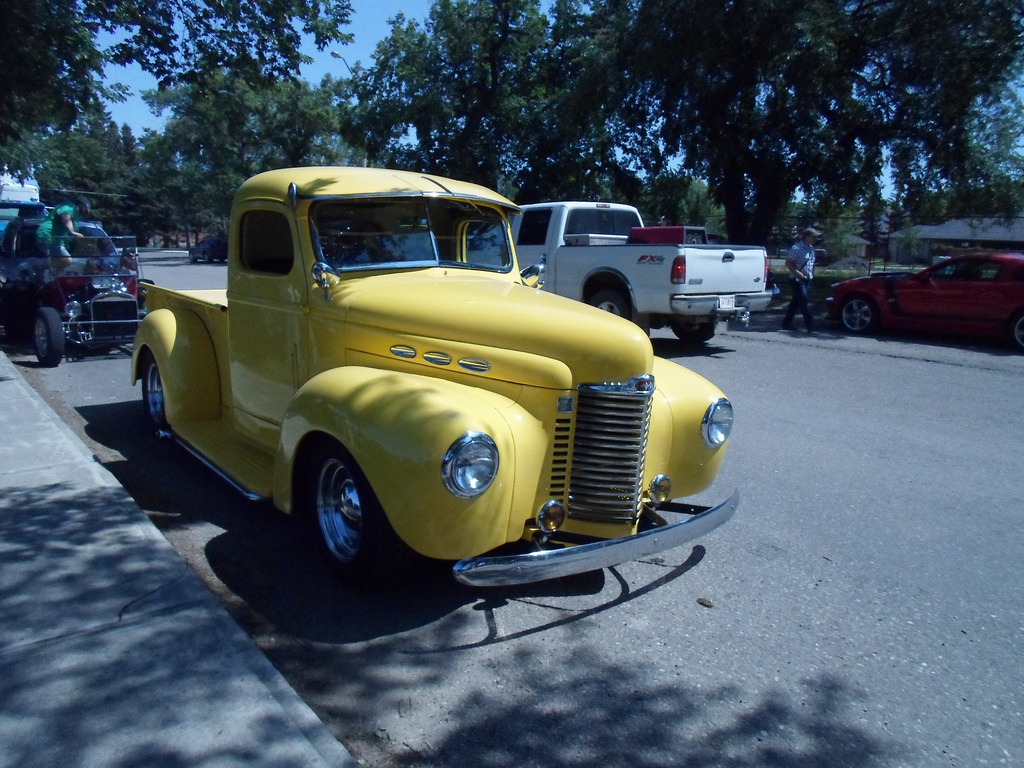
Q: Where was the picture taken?
A: It was taken at the pavement.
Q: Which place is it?
A: It is a pavement.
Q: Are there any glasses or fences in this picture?
A: No, there are no fences or glasses.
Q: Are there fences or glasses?
A: No, there are no fences or glasses.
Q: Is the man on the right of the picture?
A: Yes, the man is on the right of the image.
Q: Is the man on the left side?
A: No, the man is on the right of the image.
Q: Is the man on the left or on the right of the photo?
A: The man is on the right of the image.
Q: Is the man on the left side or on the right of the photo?
A: The man is on the right of the image.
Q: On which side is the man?
A: The man is on the right of the image.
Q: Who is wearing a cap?
A: The man is wearing a cap.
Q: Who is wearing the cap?
A: The man is wearing a cap.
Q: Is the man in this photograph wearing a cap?
A: Yes, the man is wearing a cap.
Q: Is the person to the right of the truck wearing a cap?
A: Yes, the man is wearing a cap.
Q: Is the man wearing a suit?
A: No, the man is wearing a cap.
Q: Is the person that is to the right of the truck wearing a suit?
A: No, the man is wearing a cap.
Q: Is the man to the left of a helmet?
A: No, the man is to the left of the car.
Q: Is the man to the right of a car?
A: No, the man is to the left of a car.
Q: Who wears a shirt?
A: The man wears a shirt.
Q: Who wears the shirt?
A: The man wears a shirt.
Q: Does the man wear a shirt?
A: Yes, the man wears a shirt.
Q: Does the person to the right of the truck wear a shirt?
A: Yes, the man wears a shirt.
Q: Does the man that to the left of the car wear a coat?
A: No, the man wears a shirt.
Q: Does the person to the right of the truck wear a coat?
A: No, the man wears a shirt.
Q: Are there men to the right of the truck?
A: Yes, there is a man to the right of the truck.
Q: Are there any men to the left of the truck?
A: No, the man is to the right of the truck.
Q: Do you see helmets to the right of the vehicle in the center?
A: No, there is a man to the right of the truck.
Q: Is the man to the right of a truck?
A: Yes, the man is to the right of a truck.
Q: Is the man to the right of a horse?
A: No, the man is to the right of a truck.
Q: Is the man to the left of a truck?
A: No, the man is to the right of a truck.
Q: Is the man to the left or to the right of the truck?
A: The man is to the right of the truck.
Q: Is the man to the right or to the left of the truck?
A: The man is to the right of the truck.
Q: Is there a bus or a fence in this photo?
A: No, there are no fences or buses.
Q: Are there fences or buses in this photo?
A: No, there are no fences or buses.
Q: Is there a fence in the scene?
A: No, there are no fences.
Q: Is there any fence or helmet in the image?
A: No, there are no fences or helmets.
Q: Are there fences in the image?
A: No, there are no fences.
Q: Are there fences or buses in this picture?
A: No, there are no fences or buses.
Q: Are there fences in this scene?
A: No, there are no fences.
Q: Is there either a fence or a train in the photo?
A: No, there are no fences or trains.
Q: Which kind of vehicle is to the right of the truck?
A: The vehicles are cars.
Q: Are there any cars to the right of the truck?
A: Yes, there are cars to the right of the truck.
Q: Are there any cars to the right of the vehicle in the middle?
A: Yes, there are cars to the right of the truck.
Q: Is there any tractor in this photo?
A: No, there are no tractors.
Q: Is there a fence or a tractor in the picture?
A: No, there are no tractors or fences.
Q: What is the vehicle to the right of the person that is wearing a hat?
A: The vehicle is a car.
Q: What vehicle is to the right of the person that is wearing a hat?
A: The vehicle is a car.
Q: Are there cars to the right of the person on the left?
A: Yes, there is a car to the right of the person.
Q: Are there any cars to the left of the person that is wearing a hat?
A: No, the car is to the right of the person.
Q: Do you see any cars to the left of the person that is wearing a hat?
A: No, the car is to the right of the person.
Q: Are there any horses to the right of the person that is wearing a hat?
A: No, there is a car to the right of the person.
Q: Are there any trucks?
A: Yes, there is a truck.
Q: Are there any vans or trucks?
A: Yes, there is a truck.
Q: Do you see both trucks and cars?
A: Yes, there are both a truck and cars.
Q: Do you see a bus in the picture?
A: No, there are no buses.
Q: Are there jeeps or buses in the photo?
A: No, there are no buses or jeeps.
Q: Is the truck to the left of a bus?
A: No, the truck is to the left of the car.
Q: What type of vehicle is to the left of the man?
A: The vehicle is a truck.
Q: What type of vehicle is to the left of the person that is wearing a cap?
A: The vehicle is a truck.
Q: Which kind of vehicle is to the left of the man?
A: The vehicle is a truck.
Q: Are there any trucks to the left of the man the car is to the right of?
A: Yes, there is a truck to the left of the man.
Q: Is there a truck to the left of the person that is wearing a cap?
A: Yes, there is a truck to the left of the man.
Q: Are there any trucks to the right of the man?
A: No, the truck is to the left of the man.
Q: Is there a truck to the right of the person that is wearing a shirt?
A: No, the truck is to the left of the man.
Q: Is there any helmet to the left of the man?
A: No, there is a truck to the left of the man.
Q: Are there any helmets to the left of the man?
A: No, there is a truck to the left of the man.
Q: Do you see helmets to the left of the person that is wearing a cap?
A: No, there is a truck to the left of the man.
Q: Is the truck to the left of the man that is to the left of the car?
A: Yes, the truck is to the left of the man.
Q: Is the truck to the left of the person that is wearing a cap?
A: Yes, the truck is to the left of the man.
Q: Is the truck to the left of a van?
A: No, the truck is to the left of the man.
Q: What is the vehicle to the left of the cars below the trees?
A: The vehicle is a truck.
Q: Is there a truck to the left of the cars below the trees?
A: Yes, there is a truck to the left of the cars.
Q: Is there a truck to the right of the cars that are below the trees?
A: No, the truck is to the left of the cars.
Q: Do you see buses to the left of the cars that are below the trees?
A: No, there is a truck to the left of the cars.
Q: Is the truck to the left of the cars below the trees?
A: Yes, the truck is to the left of the cars.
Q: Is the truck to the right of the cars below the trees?
A: No, the truck is to the left of the cars.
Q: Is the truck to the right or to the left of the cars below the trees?
A: The truck is to the left of the cars.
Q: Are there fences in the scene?
A: No, there are no fences.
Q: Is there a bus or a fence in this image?
A: No, there are no fences or buses.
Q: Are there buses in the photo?
A: No, there are no buses.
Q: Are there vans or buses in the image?
A: No, there are no buses or vans.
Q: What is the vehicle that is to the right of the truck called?
A: The vehicle is a car.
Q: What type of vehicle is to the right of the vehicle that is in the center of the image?
A: The vehicle is a car.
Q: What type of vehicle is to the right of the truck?
A: The vehicle is a car.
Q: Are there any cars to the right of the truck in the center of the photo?
A: Yes, there is a car to the right of the truck.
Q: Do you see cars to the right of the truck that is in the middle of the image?
A: Yes, there is a car to the right of the truck.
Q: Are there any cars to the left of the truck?
A: No, the car is to the right of the truck.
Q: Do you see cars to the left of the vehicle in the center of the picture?
A: No, the car is to the right of the truck.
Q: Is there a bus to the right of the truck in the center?
A: No, there is a car to the right of the truck.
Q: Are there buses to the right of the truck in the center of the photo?
A: No, there is a car to the right of the truck.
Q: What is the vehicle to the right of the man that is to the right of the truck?
A: The vehicle is a car.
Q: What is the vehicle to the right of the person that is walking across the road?
A: The vehicle is a car.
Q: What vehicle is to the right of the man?
A: The vehicle is a car.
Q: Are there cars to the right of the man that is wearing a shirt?
A: Yes, there is a car to the right of the man.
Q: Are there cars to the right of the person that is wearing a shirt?
A: Yes, there is a car to the right of the man.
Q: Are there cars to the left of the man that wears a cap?
A: No, the car is to the right of the man.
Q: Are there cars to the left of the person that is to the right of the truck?
A: No, the car is to the right of the man.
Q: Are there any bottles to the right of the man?
A: No, there is a car to the right of the man.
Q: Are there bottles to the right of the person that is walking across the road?
A: No, there is a car to the right of the man.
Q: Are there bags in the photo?
A: No, there are no bags.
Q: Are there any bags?
A: No, there are no bags.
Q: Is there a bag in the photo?
A: No, there are no bags.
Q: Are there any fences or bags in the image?
A: No, there are no bags or fences.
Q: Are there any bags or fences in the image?
A: No, there are no bags or fences.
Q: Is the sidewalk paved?
A: Yes, the sidewalk is paved.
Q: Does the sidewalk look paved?
A: Yes, the sidewalk is paved.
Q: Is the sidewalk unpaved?
A: No, the sidewalk is paved.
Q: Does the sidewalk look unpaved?
A: No, the sidewalk is paved.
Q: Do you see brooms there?
A: No, there are no brooms.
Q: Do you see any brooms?
A: No, there are no brooms.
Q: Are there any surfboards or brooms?
A: No, there are no brooms or surfboards.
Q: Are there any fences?
A: No, there are no fences.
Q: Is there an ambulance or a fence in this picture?
A: No, there are no fences or ambulances.